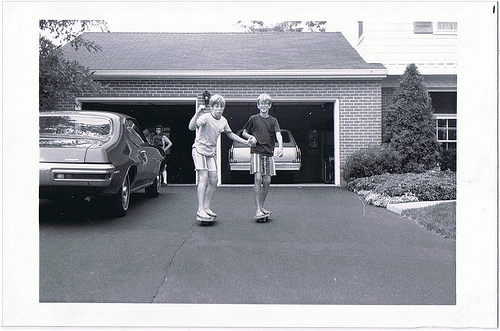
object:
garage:
[39, 32, 389, 187]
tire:
[106, 176, 130, 217]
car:
[39, 110, 166, 217]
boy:
[188, 94, 256, 219]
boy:
[241, 93, 283, 216]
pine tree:
[380, 63, 443, 171]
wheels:
[201, 221, 212, 226]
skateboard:
[253, 212, 269, 221]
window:
[39, 115, 114, 148]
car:
[227, 128, 301, 171]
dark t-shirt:
[242, 113, 280, 157]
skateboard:
[196, 214, 216, 225]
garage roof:
[58, 32, 388, 81]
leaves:
[400, 99, 427, 138]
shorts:
[249, 153, 277, 177]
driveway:
[39, 184, 456, 304]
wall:
[48, 80, 383, 186]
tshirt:
[191, 113, 232, 157]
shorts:
[191, 148, 217, 173]